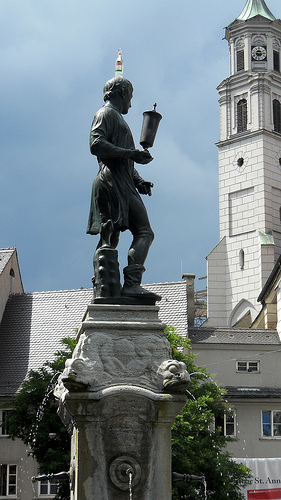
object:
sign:
[222, 453, 280, 498]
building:
[0, 251, 278, 498]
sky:
[11, 7, 72, 181]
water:
[189, 367, 208, 377]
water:
[185, 387, 197, 399]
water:
[45, 372, 54, 400]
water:
[126, 469, 137, 493]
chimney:
[180, 272, 194, 327]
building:
[187, 326, 278, 458]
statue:
[79, 73, 165, 305]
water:
[15, 365, 63, 498]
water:
[181, 387, 230, 495]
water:
[124, 471, 133, 495]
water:
[190, 370, 257, 491]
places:
[14, 371, 257, 496]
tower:
[200, 1, 277, 327]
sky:
[3, 3, 220, 265]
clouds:
[1, 7, 101, 87]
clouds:
[169, 5, 214, 146]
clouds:
[10, 31, 70, 139]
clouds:
[156, 142, 212, 242]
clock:
[248, 45, 265, 62]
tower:
[229, 0, 279, 74]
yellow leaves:
[15, 134, 64, 204]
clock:
[237, 39, 272, 75]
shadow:
[2, 290, 29, 392]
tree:
[12, 312, 259, 495]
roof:
[6, 291, 71, 384]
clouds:
[157, 142, 210, 194]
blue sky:
[0, 0, 279, 292]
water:
[77, 236, 183, 340]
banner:
[215, 451, 280, 498]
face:
[119, 89, 133, 117]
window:
[213, 406, 236, 437]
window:
[260, 407, 280, 438]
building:
[183, 1, 280, 458]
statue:
[86, 74, 164, 304]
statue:
[72, 76, 182, 314]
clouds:
[0, 0, 281, 211]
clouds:
[0, 0, 278, 288]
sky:
[0, 0, 278, 289]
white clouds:
[167, 144, 206, 185]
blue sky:
[1, 0, 279, 325]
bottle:
[114, 47, 123, 78]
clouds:
[0, 0, 242, 294]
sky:
[0, 0, 281, 328]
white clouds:
[157, 144, 210, 186]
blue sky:
[13, 1, 221, 75]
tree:
[0, 322, 252, 498]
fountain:
[8, 44, 249, 499]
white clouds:
[163, 137, 203, 191]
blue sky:
[126, 25, 176, 80]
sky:
[2, 3, 89, 248]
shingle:
[89, 291, 92, 296]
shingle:
[77, 290, 84, 296]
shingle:
[67, 291, 71, 296]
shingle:
[49, 292, 54, 297]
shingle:
[49, 311, 53, 317]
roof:
[0, 288, 93, 406]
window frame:
[6, 462, 19, 496]